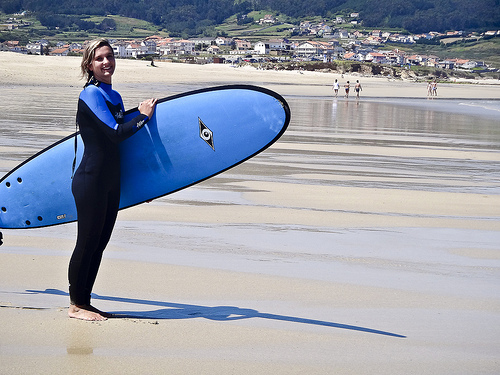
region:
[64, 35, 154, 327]
a lady in wet suit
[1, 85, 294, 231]
a blue surf board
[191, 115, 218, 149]
a logo on board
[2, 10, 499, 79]
buildings by beach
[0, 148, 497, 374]
the wet sand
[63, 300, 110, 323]
bare feet in sand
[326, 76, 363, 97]
three people in water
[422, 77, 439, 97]
two people walking on beach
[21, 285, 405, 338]
a shadow in the sand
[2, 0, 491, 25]
trees in the horizon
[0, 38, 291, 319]
the woman holding surfboard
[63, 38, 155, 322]
person is wearing wetsuit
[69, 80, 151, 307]
wetsuit is black and blue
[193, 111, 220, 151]
white and black logo on surfboard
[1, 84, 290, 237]
surfboard is black and blue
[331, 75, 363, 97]
three people running across beach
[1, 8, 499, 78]
several houses line hilltop in background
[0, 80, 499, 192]
water flows across beach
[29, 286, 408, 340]
woman and board casting shadow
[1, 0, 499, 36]
trees behind houses on hill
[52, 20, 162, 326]
woman wears a blue and black suit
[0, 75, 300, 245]
a blue surfboard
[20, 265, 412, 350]
a shadow on the sand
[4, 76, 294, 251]
surfboard has black border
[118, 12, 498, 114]
houses in front the sea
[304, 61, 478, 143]
people in front the ocean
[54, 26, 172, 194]
woman is blonde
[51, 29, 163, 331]
woman is barefeet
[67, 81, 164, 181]
top of wetsuit is blue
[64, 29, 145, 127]
a happy smiling woman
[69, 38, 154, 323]
A woman on the beach.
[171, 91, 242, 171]
part of the blue surfboard.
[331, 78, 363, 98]
Three people walking on the beach.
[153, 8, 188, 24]
Green trees in the distance.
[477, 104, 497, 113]
Part of the water.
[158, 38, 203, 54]
Houses in the distance.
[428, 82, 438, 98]
Two people walking on the beach.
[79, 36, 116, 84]
The woman's head.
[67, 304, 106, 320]
The woman's bare feet.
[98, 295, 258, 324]
A shadow of the woman.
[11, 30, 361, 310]
woman standing on beach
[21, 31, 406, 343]
woman standing on beach holding surf board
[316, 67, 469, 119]
people walking on beach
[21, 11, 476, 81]
houses in the mountains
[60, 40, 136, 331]
woman wearing black and blue wetsuit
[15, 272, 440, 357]
woman's shadow on the ground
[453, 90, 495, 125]
wave coming in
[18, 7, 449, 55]
mountains with lots of foilage and trees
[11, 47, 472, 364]
tide is out pretty far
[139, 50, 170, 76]
person sitting on beach alone